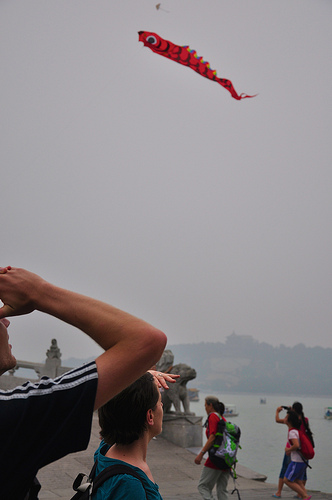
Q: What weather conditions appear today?
A: It is cloudy.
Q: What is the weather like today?
A: It is cloudy.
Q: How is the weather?
A: It is cloudy.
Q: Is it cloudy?
A: Yes, it is cloudy.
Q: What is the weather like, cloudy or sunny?
A: It is cloudy.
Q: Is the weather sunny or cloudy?
A: It is cloudy.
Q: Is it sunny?
A: No, it is cloudy.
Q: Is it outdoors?
A: Yes, it is outdoors.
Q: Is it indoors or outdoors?
A: It is outdoors.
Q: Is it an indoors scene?
A: No, it is outdoors.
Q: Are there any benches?
A: No, there are no benches.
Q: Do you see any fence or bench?
A: No, there are no benches or fences.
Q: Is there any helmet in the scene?
A: No, there are no helmets.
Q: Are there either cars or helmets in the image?
A: No, there are no helmets or cars.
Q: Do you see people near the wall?
A: Yes, there is a person near the wall.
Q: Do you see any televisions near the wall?
A: No, there is a person near the wall.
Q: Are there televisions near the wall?
A: No, there is a person near the wall.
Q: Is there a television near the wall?
A: No, there is a person near the wall.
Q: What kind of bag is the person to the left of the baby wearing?
A: The person is wearing a backpack.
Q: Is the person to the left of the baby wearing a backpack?
A: Yes, the person is wearing a backpack.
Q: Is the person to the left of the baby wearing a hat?
A: No, the person is wearing a backpack.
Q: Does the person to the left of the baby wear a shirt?
A: Yes, the person wears a shirt.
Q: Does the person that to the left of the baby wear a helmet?
A: No, the person wears a shirt.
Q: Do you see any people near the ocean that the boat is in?
A: Yes, there is a person near the ocean.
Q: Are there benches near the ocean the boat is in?
A: No, there is a person near the ocean.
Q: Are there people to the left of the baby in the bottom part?
A: Yes, there is a person to the left of the baby.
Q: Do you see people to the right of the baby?
A: No, the person is to the left of the baby.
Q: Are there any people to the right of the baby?
A: No, the person is to the left of the baby.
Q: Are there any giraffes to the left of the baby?
A: No, there is a person to the left of the baby.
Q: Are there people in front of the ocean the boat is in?
A: Yes, there is a person in front of the ocean.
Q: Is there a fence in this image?
A: No, there are no fences.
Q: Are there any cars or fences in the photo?
A: No, there are no fences or cars.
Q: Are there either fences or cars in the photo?
A: No, there are no fences or cars.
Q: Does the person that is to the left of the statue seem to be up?
A: Yes, the person is up.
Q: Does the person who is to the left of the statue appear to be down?
A: No, the person is up.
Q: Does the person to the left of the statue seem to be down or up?
A: The person is up.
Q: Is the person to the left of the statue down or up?
A: The person is up.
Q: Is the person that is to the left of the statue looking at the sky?
A: Yes, the person is looking at the sky.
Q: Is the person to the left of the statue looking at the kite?
A: Yes, the person is looking at the kite.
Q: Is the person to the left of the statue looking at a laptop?
A: No, the person is looking at the kite.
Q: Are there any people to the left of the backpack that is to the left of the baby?
A: Yes, there is a person to the left of the backpack.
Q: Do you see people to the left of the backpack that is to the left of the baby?
A: Yes, there is a person to the left of the backpack.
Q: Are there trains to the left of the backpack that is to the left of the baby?
A: No, there is a person to the left of the backpack.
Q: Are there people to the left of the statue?
A: Yes, there is a person to the left of the statue.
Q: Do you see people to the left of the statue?
A: Yes, there is a person to the left of the statue.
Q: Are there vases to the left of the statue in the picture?
A: No, there is a person to the left of the statue.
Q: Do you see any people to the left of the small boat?
A: Yes, there is a person to the left of the boat.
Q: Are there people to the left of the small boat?
A: Yes, there is a person to the left of the boat.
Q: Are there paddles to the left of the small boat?
A: No, there is a person to the left of the boat.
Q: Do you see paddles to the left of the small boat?
A: No, there is a person to the left of the boat.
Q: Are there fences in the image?
A: No, there are no fences.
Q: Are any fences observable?
A: No, there are no fences.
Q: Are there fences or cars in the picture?
A: No, there are no fences or cars.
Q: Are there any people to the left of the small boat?
A: Yes, there is a person to the left of the boat.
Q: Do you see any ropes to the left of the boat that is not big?
A: No, there is a person to the left of the boat.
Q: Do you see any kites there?
A: Yes, there is a kite.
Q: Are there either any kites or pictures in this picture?
A: Yes, there is a kite.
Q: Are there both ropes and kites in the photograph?
A: No, there is a kite but no ropes.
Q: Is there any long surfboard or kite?
A: Yes, there is a long kite.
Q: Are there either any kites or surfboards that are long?
A: Yes, the kite is long.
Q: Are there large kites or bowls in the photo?
A: Yes, there is a large kite.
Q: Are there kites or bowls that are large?
A: Yes, the kite is large.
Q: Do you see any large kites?
A: Yes, there is a large kite.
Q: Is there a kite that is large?
A: Yes, there is a kite that is large.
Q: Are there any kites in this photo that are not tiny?
A: Yes, there is a large kite.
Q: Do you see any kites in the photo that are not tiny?
A: Yes, there is a large kite.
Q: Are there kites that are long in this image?
A: Yes, there is a long kite.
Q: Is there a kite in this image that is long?
A: Yes, there is a kite that is long.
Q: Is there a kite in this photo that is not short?
A: Yes, there is a long kite.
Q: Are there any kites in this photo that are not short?
A: Yes, there is a long kite.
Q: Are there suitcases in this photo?
A: No, there are no suitcases.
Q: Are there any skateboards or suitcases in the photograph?
A: No, there are no suitcases or skateboards.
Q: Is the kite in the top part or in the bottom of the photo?
A: The kite is in the top of the image.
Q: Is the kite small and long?
A: No, the kite is long but large.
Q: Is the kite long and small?
A: No, the kite is long but large.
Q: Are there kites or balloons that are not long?
A: No, there is a kite but it is long.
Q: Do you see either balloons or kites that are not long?
A: No, there is a kite but it is long.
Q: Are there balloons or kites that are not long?
A: No, there is a kite but it is long.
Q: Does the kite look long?
A: Yes, the kite is long.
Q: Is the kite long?
A: Yes, the kite is long.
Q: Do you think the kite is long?
A: Yes, the kite is long.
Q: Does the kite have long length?
A: Yes, the kite is long.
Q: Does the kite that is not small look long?
A: Yes, the kite is long.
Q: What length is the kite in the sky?
A: The kite is long.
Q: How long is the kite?
A: The kite is long.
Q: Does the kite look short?
A: No, the kite is long.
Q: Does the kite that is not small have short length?
A: No, the kite is long.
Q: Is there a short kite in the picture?
A: No, there is a kite but it is long.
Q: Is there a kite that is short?
A: No, there is a kite but it is long.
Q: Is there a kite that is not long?
A: No, there is a kite but it is long.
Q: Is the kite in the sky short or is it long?
A: The kite is long.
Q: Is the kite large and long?
A: Yes, the kite is large and long.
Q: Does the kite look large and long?
A: Yes, the kite is large and long.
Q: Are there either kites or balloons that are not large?
A: No, there is a kite but it is large.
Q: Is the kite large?
A: Yes, the kite is large.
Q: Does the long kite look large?
A: Yes, the kite is large.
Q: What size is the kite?
A: The kite is large.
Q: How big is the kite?
A: The kite is large.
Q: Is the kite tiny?
A: No, the kite is large.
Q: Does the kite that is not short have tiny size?
A: No, the kite is large.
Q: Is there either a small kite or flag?
A: No, there is a kite but it is large.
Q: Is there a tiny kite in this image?
A: No, there is a kite but it is large.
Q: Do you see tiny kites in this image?
A: No, there is a kite but it is large.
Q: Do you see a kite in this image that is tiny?
A: No, there is a kite but it is large.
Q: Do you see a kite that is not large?
A: No, there is a kite but it is large.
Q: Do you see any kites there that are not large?
A: No, there is a kite but it is large.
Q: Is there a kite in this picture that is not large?
A: No, there is a kite but it is large.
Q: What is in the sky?
A: The kite is in the sky.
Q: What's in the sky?
A: The kite is in the sky.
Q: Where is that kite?
A: The kite is in the sky.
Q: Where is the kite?
A: The kite is in the sky.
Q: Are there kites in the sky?
A: Yes, there is a kite in the sky.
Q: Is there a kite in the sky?
A: Yes, there is a kite in the sky.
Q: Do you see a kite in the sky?
A: Yes, there is a kite in the sky.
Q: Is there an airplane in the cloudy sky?
A: No, there is a kite in the sky.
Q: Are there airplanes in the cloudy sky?
A: No, there is a kite in the sky.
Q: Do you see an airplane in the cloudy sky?
A: No, there is a kite in the sky.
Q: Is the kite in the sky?
A: Yes, the kite is in the sky.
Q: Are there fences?
A: No, there are no fences.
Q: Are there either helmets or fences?
A: No, there are no fences or helmets.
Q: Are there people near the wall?
A: Yes, there is a person near the wall.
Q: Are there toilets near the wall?
A: No, there is a person near the wall.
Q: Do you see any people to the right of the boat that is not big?
A: Yes, there is a person to the right of the boat.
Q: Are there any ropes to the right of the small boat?
A: No, there is a person to the right of the boat.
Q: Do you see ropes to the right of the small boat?
A: No, there is a person to the right of the boat.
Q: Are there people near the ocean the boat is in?
A: Yes, there is a person near the ocean.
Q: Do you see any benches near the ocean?
A: No, there is a person near the ocean.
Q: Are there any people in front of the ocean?
A: Yes, there is a person in front of the ocean.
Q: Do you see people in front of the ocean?
A: Yes, there is a person in front of the ocean.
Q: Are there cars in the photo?
A: No, there are no cars.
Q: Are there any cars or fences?
A: No, there are no cars or fences.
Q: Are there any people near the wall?
A: Yes, there is a person near the wall.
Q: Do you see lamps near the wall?
A: No, there is a person near the wall.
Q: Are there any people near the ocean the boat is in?
A: Yes, there is a person near the ocean.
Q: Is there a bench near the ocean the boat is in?
A: No, there is a person near the ocean.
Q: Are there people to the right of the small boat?
A: Yes, there is a person to the right of the boat.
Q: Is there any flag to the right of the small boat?
A: No, there is a person to the right of the boat.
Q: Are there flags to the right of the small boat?
A: No, there is a person to the right of the boat.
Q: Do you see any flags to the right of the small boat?
A: No, there is a person to the right of the boat.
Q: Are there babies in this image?
A: Yes, there is a baby.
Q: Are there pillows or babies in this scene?
A: Yes, there is a baby.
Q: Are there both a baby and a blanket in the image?
A: No, there is a baby but no blankets.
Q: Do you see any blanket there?
A: No, there are no blankets.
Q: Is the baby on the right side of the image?
A: Yes, the baby is on the right of the image.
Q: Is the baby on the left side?
A: No, the baby is on the right of the image.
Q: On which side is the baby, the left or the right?
A: The baby is on the right of the image.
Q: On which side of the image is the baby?
A: The baby is on the right of the image.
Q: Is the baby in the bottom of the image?
A: Yes, the baby is in the bottom of the image.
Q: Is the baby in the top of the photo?
A: No, the baby is in the bottom of the image.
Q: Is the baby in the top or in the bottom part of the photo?
A: The baby is in the bottom of the image.